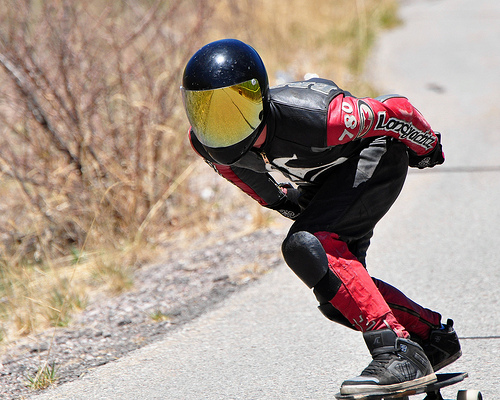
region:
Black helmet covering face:
[173, 35, 275, 163]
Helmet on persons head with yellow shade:
[181, 37, 273, 167]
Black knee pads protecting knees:
[277, 231, 334, 294]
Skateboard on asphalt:
[319, 369, 487, 398]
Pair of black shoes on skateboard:
[337, 314, 464, 396]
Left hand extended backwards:
[320, 91, 452, 173]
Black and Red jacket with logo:
[196, 74, 455, 216]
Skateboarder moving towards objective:
[175, 36, 472, 396]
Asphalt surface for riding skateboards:
[28, 0, 498, 398]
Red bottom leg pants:
[306, 229, 446, 356]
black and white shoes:
[343, 322, 478, 397]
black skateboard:
[336, 360, 468, 396]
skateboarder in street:
[181, 38, 471, 396]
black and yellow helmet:
[177, 34, 271, 156]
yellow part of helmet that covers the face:
[183, 83, 258, 151]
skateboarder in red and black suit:
[181, 38, 468, 398]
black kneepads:
[271, 229, 351, 317]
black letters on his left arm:
[364, 107, 439, 162]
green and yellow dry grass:
[0, 4, 380, 356]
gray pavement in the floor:
[16, 8, 490, 398]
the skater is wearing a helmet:
[181, 40, 270, 158]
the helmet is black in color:
[178, 39, 273, 156]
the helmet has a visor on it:
[178, 75, 265, 150]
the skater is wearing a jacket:
[188, 75, 442, 219]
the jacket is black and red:
[183, 79, 445, 216]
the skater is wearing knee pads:
[281, 221, 361, 289]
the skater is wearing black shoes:
[340, 325, 438, 388]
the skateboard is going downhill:
[331, 365, 485, 395]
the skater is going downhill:
[161, 36, 493, 398]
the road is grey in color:
[43, 13, 492, 399]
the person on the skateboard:
[141, 25, 485, 375]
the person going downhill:
[136, 20, 472, 394]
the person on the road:
[193, 27, 474, 398]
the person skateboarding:
[141, 25, 463, 397]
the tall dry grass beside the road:
[36, 18, 189, 190]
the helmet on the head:
[138, 13, 298, 172]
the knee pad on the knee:
[231, 213, 352, 315]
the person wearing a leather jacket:
[158, 68, 463, 218]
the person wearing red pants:
[233, 193, 460, 371]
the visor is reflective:
[156, 78, 273, 140]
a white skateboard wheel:
[459, 388, 481, 398]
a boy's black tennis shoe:
[335, 329, 438, 399]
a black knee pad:
[279, 229, 336, 284]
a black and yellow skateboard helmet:
[181, 38, 273, 157]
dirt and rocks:
[0, 227, 292, 399]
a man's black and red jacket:
[184, 82, 442, 218]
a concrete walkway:
[36, 0, 498, 399]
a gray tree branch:
[0, 54, 112, 201]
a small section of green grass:
[35, 270, 77, 323]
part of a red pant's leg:
[313, 234, 403, 337]